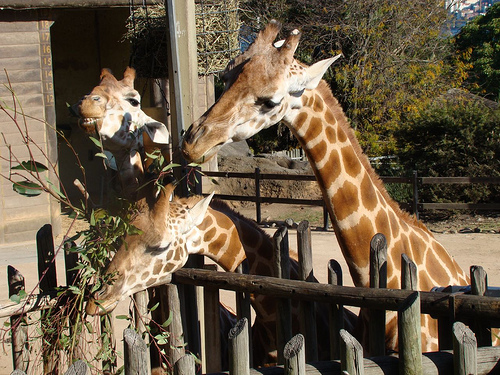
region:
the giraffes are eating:
[39, 17, 471, 368]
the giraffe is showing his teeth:
[78, 100, 101, 133]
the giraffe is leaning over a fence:
[52, 180, 321, 349]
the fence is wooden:
[172, 220, 499, 374]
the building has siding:
[3, 10, 43, 240]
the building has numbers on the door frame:
[22, 16, 64, 118]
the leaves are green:
[25, 163, 127, 255]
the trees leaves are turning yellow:
[343, 16, 463, 143]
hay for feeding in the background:
[127, 2, 250, 79]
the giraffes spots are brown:
[314, 128, 395, 264]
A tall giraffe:
[185, 18, 498, 356]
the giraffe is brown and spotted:
[186, 22, 498, 347]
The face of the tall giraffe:
[182, 21, 328, 161]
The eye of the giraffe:
[257, 91, 282, 112]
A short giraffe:
[75, 181, 363, 365]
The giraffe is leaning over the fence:
[85, 174, 360, 373]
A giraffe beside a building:
[86, 71, 169, 176]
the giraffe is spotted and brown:
[94, 186, 350, 356]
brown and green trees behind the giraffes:
[335, 10, 497, 181]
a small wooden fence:
[60, 243, 498, 373]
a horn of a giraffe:
[280, 20, 307, 65]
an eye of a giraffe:
[139, 231, 177, 259]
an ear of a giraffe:
[297, 45, 343, 95]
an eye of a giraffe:
[252, 85, 282, 110]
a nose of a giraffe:
[175, 125, 220, 151]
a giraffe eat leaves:
[57, 265, 138, 331]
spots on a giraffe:
[335, 157, 376, 252]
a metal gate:
[239, 163, 330, 233]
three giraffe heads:
[65, 45, 316, 310]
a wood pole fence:
[220, 221, 333, 356]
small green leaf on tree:
[6, 171, 58, 198]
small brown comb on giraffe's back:
[328, 90, 391, 197]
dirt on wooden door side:
[20, 45, 60, 138]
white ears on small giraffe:
[172, 183, 226, 254]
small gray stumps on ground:
[218, 305, 368, 362]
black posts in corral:
[216, 145, 478, 240]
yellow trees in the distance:
[351, 55, 459, 132]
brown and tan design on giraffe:
[295, 118, 429, 212]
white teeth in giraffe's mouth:
[70, 107, 133, 146]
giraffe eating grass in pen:
[55, 52, 372, 318]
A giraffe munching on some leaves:
[64, 181, 227, 333]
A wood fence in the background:
[240, 160, 498, 221]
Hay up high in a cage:
[113, 2, 248, 82]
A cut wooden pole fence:
[261, 260, 463, 355]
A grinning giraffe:
[68, 69, 165, 156]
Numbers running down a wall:
[33, 13, 61, 110]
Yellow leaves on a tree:
[331, 19, 459, 168]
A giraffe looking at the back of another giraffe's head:
[157, 17, 364, 171]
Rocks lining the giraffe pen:
[425, 227, 498, 259]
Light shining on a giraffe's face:
[105, 76, 160, 146]